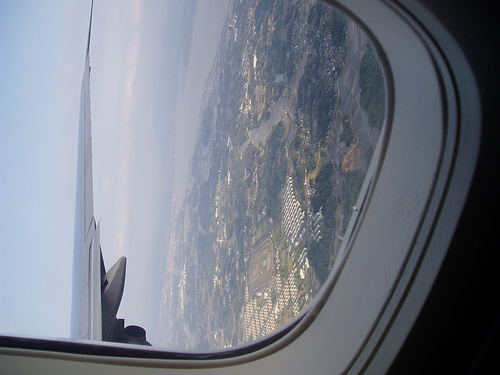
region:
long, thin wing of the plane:
[55, 6, 147, 345]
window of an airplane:
[3, 4, 490, 374]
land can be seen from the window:
[144, 2, 382, 364]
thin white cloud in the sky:
[112, 11, 150, 248]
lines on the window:
[418, 52, 472, 234]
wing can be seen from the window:
[64, 3, 165, 366]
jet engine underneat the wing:
[48, 223, 178, 351]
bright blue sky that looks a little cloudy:
[1, 6, 188, 373]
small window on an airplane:
[1, 4, 471, 371]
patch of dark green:
[285, 68, 338, 148]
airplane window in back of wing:
[22, 7, 487, 363]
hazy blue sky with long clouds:
[17, 20, 157, 265]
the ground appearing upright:
[162, 12, 307, 323]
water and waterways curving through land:
[166, 10, 311, 240]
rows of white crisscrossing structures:
[237, 270, 302, 327]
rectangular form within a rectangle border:
[241, 232, 276, 292]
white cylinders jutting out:
[270, 171, 320, 241]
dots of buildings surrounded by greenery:
[290, 111, 330, 157]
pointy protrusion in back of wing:
[87, 251, 129, 312]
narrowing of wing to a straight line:
[72, 1, 102, 294]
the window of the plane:
[12, 3, 476, 373]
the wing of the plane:
[48, 11, 158, 357]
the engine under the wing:
[102, 325, 163, 350]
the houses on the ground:
[286, 187, 308, 314]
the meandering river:
[176, 48, 302, 195]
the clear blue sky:
[2, 13, 47, 303]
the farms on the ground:
[312, 71, 384, 163]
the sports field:
[225, 221, 283, 292]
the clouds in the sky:
[107, 30, 168, 179]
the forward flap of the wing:
[48, 238, 122, 350]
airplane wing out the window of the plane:
[46, 37, 168, 346]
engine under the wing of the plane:
[116, 323, 153, 350]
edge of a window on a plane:
[359, 53, 471, 333]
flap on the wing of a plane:
[79, 214, 114, 343]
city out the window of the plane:
[209, 194, 297, 311]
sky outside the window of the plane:
[7, 106, 67, 251]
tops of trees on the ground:
[350, 49, 384, 111]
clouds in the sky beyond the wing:
[104, 46, 164, 191]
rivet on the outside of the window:
[346, 199, 365, 216]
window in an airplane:
[6, 2, 477, 374]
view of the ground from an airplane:
[120, 0, 374, 374]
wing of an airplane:
[61, 0, 143, 342]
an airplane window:
[9, 5, 444, 373]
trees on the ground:
[147, 5, 379, 364]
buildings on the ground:
[144, 0, 376, 357]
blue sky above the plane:
[0, 5, 195, 335]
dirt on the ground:
[137, 5, 415, 365]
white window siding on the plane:
[4, 2, 476, 374]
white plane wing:
[58, 4, 120, 346]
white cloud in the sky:
[86, 5, 162, 290]